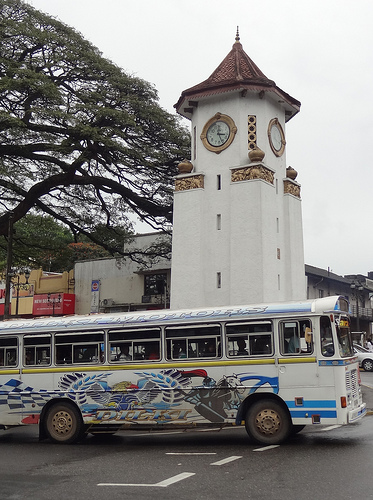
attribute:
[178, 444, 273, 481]
lines — white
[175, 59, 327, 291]
tower — white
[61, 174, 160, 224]
bare branch — large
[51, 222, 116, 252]
bare branch — large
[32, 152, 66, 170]
bare branch — large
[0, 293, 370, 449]
bus — white, older, painted, ornate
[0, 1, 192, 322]
tree — large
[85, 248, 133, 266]
roof — pointed, tiled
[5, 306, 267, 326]
bus company — white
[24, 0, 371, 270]
sky — white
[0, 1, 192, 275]
tree — large, green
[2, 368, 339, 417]
design — colorful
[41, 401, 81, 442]
tire — black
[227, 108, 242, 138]
frame — gold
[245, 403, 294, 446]
tire — large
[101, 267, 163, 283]
line — white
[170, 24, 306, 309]
clock tower — tall, white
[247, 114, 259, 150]
design — gold